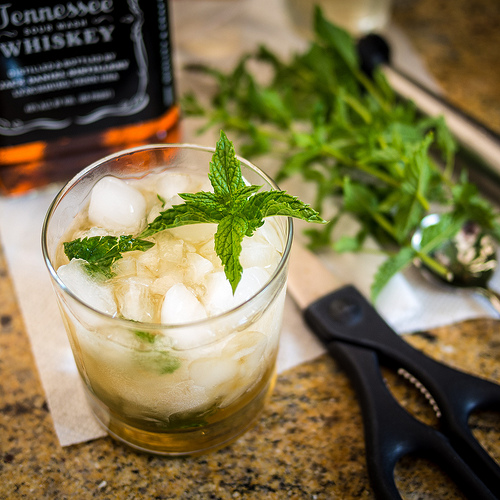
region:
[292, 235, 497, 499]
a pair of black handled scissors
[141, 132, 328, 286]
a mint leaf in a drink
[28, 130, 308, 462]
a glass with liquid and ice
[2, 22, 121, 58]
the word whiskey printed on a label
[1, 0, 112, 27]
the word Tennessee printed on a label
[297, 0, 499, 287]
stalks of mint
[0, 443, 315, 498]
a granite counter top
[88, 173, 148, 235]
a cloudy ice cube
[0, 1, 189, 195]
bottle of whiskey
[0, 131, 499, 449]
a paper towel on a counter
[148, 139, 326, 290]
Peppermint leaf on top of ice cubes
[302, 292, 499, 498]
Handle of a pair of scissors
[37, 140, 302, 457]
Clear glass of whisky on ice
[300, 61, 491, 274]
Bunch of fresh peppermint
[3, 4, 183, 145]
Bottle of whiskey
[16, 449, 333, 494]
Granite counter top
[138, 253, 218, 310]
Ice cubes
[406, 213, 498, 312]
Silver colored spoon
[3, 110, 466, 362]
White paper towel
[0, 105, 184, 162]
Brown liquid at the bottom of a bottle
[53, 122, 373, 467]
a drink with ice cubes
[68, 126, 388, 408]
an iced drink with leaves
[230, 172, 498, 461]
scissors next to a glass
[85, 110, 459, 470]
black scissors next to an iced drink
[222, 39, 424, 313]
leaves in the blurred background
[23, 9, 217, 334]
an alcoholic drink with leaves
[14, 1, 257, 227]
Jack Daniel bottle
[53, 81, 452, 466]
a homemade iced alcoholic drink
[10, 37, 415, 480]
a mixed drink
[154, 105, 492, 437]
metal scissors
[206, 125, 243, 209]
the green leaf of a tree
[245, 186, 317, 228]
the green leaf of a tree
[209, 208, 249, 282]
the green leaf of a tree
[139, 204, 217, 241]
the green leaf of a tree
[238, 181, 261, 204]
the green leaf of a tree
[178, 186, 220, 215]
the green leaf of a tree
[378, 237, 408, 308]
the green leaf of a tree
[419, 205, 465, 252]
the green leaf of a tree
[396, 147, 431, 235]
the green leaf of a tree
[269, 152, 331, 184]
the green leaf of a tree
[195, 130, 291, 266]
Cut green mint leaves in a drink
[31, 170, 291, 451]
A drink in a glass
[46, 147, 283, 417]
A lot of ice in a drink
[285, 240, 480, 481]
Black handled scissors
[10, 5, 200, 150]
A whisky bottle on a counter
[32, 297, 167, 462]
A paper towel under a glass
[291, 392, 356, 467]
A marble patterned countertop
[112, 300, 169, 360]
A mint leaf hiding in the ice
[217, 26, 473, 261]
A bunch of uncut mint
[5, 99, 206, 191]
The reflection of whiskey in its bottle